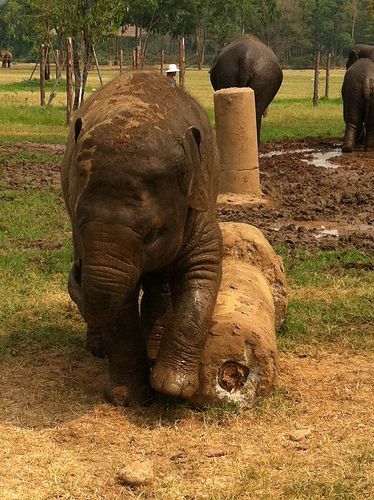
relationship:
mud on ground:
[207, 137, 373, 257] [2, 61, 373, 499]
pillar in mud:
[208, 84, 269, 207] [207, 137, 373, 257]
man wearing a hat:
[162, 61, 180, 84] [166, 62, 181, 75]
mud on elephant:
[72, 66, 173, 147] [61, 70, 222, 415]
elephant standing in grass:
[2, 48, 16, 70] [4, 64, 372, 146]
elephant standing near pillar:
[61, 70, 222, 415] [201, 218, 288, 400]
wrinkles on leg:
[171, 246, 224, 283] [149, 241, 223, 399]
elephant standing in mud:
[209, 31, 283, 154] [207, 137, 373, 257]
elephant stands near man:
[209, 31, 283, 154] [162, 61, 180, 84]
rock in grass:
[115, 459, 158, 487] [1, 348, 373, 500]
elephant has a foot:
[61, 70, 222, 415] [150, 364, 202, 401]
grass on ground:
[4, 64, 372, 146] [2, 61, 373, 499]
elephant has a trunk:
[61, 70, 222, 415] [78, 253, 164, 411]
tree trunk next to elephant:
[173, 35, 189, 91] [209, 31, 283, 154]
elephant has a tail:
[209, 31, 283, 154] [232, 63, 255, 87]